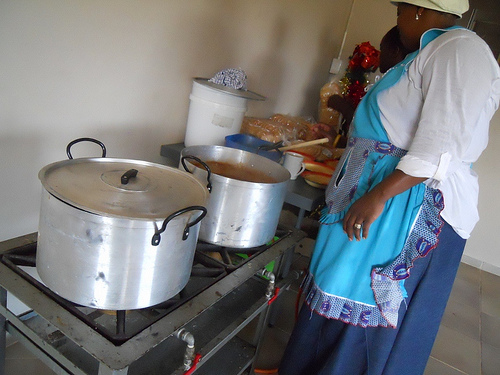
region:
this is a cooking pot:
[37, 133, 209, 314]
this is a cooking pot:
[178, 135, 290, 250]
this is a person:
[282, 0, 492, 370]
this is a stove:
[3, 135, 294, 372]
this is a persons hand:
[330, 35, 498, 240]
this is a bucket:
[180, 70, 245, 150]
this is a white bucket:
[186, 70, 252, 156]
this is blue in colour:
[302, 327, 352, 364]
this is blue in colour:
[381, 335, 413, 365]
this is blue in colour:
[440, 251, 452, 289]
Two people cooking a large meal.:
[16, 23, 491, 373]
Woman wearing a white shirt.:
[362, 11, 485, 231]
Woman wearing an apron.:
[305, 17, 471, 327]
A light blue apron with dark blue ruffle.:
[301, 49, 448, 333]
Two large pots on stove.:
[28, 134, 295, 309]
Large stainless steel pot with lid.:
[27, 130, 207, 305]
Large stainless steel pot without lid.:
[184, 140, 290, 252]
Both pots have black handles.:
[58, 133, 280, 250]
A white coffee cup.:
[278, 148, 305, 180]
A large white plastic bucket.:
[179, 70, 244, 145]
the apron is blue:
[318, 40, 438, 354]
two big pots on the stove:
[18, 93, 329, 367]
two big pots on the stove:
[23, 110, 313, 324]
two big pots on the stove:
[38, 119, 313, 319]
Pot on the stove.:
[26, 128, 210, 320]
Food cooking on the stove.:
[174, 134, 294, 254]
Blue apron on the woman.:
[304, 1, 498, 335]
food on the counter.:
[250, 106, 330, 152]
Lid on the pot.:
[35, 150, 213, 223]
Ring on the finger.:
[352, 213, 369, 241]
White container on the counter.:
[180, 75, 247, 154]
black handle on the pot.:
[149, 196, 209, 253]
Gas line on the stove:
[170, 320, 203, 373]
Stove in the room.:
[0, 230, 316, 374]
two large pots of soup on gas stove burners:
[35, 136, 292, 311]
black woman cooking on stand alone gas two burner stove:
[0, 0, 498, 374]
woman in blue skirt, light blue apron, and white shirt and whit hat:
[277, 0, 497, 371]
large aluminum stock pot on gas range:
[172, 142, 288, 244]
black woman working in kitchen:
[326, 26, 408, 149]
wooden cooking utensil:
[274, 137, 328, 152]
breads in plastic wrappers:
[240, 112, 330, 142]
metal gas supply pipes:
[170, 269, 302, 374]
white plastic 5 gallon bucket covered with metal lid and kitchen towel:
[185, 66, 265, 143]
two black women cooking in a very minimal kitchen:
[5, 0, 497, 372]